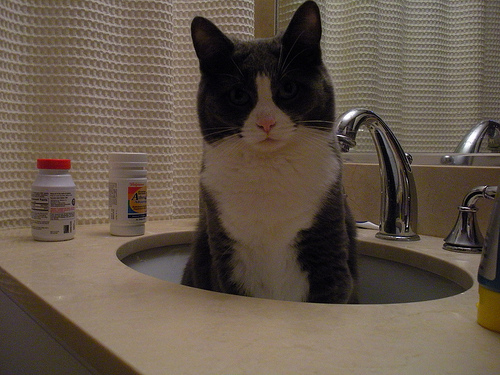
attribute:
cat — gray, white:
[183, 12, 359, 285]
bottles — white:
[28, 141, 162, 244]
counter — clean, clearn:
[20, 202, 214, 341]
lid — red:
[29, 151, 77, 179]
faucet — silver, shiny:
[329, 98, 418, 269]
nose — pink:
[256, 111, 279, 136]